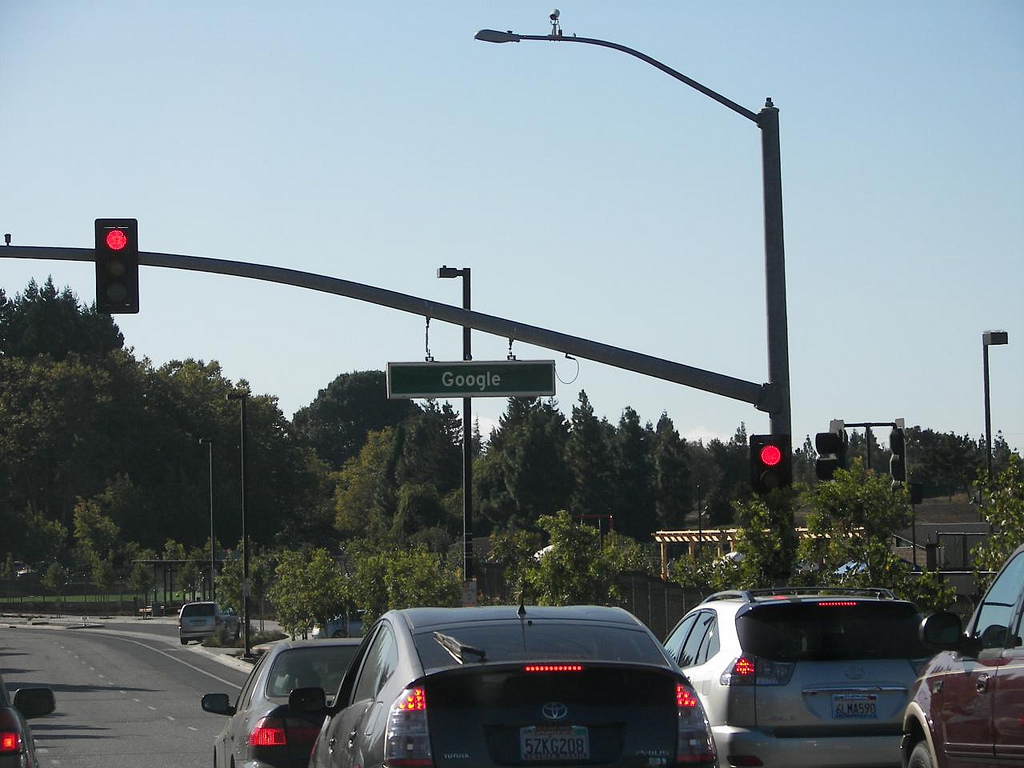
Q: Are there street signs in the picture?
A: Yes, there is a street sign.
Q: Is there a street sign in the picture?
A: Yes, there is a street sign.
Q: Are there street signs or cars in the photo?
A: Yes, there is a street sign.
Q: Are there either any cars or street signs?
A: Yes, there is a street sign.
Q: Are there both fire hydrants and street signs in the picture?
A: No, there is a street sign but no fire hydrants.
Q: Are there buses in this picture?
A: No, there are no buses.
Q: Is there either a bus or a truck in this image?
A: No, there are no buses or trucks.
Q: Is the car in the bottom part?
A: Yes, the car is in the bottom of the image.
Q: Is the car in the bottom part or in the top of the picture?
A: The car is in the bottom of the image.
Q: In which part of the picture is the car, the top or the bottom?
A: The car is in the bottom of the image.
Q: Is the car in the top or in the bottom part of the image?
A: The car is in the bottom of the image.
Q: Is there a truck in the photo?
A: No, there are no trucks.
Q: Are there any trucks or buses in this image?
A: No, there are no trucks or buses.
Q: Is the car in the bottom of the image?
A: Yes, the car is in the bottom of the image.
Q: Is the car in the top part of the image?
A: No, the car is in the bottom of the image.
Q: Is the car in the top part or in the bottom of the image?
A: The car is in the bottom of the image.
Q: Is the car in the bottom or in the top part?
A: The car is in the bottom of the image.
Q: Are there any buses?
A: No, there are no buses.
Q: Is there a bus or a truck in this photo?
A: No, there are no buses or trucks.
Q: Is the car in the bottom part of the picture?
A: Yes, the car is in the bottom of the image.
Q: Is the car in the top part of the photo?
A: No, the car is in the bottom of the image.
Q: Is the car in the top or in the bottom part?
A: The car is in the bottom of the image.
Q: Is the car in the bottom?
A: Yes, the car is in the bottom of the image.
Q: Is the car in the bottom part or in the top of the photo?
A: The car is in the bottom of the image.